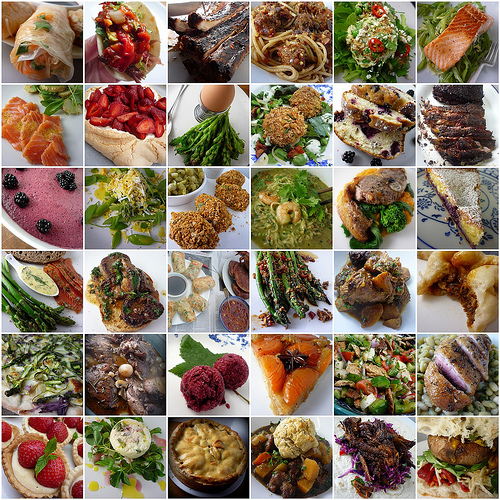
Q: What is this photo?
A: A collage of many smaller food photos.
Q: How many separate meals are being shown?
A: 36.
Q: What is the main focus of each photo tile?
A: Food.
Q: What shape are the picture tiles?
A: Square.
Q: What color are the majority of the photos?
A: Green.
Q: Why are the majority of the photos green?
A: Lots of vegetables are pictured.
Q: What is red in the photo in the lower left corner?
A: Strawberries.